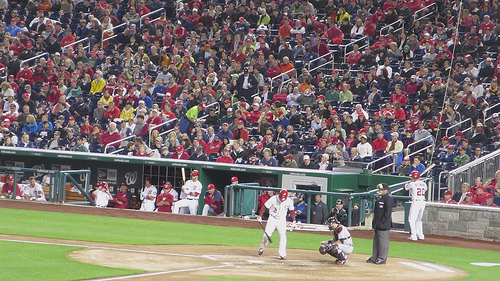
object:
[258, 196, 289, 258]
clothes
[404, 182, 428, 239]
clothes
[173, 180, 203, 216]
clothes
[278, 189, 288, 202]
helmet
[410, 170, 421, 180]
helmet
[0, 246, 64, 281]
grass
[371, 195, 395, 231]
jacket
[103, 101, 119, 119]
spectator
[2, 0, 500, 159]
stands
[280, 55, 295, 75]
spectator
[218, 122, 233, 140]
spectator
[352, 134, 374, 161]
spectator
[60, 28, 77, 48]
spectator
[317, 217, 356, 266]
man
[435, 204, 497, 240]
wall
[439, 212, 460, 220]
brick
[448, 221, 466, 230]
brick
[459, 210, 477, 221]
brick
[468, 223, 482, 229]
brick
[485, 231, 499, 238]
brick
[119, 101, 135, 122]
man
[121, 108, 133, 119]
shirt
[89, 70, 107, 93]
man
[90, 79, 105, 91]
shirt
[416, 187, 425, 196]
number 20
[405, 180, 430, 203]
shirt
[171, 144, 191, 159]
person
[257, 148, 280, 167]
person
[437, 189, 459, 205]
person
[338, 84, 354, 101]
person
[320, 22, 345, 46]
person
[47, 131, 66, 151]
person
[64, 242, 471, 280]
circle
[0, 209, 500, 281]
infield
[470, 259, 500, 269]
spot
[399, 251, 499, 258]
grass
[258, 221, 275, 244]
bat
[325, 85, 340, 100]
man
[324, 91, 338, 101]
shirt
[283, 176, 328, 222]
door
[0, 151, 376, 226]
dugout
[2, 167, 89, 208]
fence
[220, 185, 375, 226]
fence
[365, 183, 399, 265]
umpire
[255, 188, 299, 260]
batter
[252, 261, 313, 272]
dirt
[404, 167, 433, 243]
player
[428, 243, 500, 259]
deck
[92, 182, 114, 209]
teammate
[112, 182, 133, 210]
teammate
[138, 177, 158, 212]
teammate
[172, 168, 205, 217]
teammate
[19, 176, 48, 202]
teammate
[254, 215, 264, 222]
right hand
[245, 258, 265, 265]
home plate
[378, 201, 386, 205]
writing